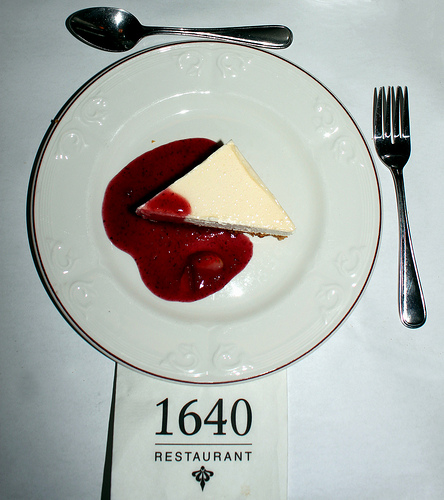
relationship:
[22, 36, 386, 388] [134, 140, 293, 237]
plate holding cheesecake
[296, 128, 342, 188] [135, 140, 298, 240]
plate with dessert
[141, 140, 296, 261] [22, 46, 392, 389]
dessert on plate